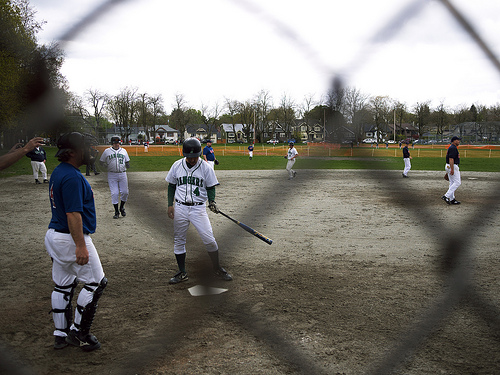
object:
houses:
[100, 118, 478, 143]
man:
[166, 135, 238, 287]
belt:
[176, 201, 204, 206]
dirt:
[0, 169, 500, 374]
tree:
[137, 93, 150, 137]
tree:
[175, 93, 185, 142]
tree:
[256, 88, 271, 146]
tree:
[415, 100, 432, 141]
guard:
[75, 275, 109, 333]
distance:
[0, 102, 500, 170]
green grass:
[219, 159, 284, 165]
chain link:
[0, 0, 500, 375]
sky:
[4, 0, 500, 117]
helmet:
[181, 138, 201, 157]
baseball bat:
[209, 204, 274, 245]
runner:
[99, 136, 130, 219]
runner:
[283, 137, 299, 180]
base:
[185, 285, 229, 297]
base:
[469, 176, 477, 180]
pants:
[44, 226, 106, 338]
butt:
[44, 229, 78, 259]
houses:
[255, 123, 313, 142]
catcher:
[43, 132, 109, 353]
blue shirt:
[47, 163, 100, 235]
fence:
[0, 142, 500, 160]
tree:
[0, 0, 110, 177]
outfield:
[287, 133, 407, 203]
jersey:
[164, 155, 221, 257]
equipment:
[54, 130, 94, 166]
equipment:
[52, 281, 73, 349]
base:
[112, 212, 120, 219]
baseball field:
[0, 140, 500, 374]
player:
[401, 144, 415, 177]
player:
[441, 135, 465, 206]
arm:
[39, 146, 47, 162]